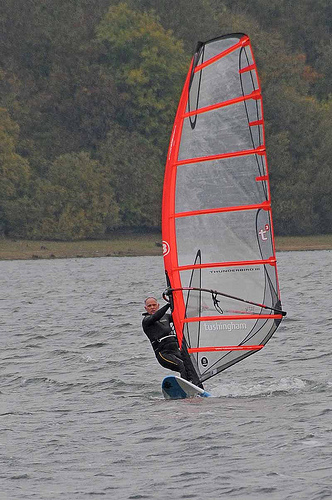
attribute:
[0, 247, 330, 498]
ocean — blue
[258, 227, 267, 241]
letter — red, white, t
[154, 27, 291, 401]
windsurfing board — clashing colors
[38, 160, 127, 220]
green tree — large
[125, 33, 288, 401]
windsurfer — determined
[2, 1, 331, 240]
trees — green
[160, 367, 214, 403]
board — blue, white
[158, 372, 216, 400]
surfboard — blue and white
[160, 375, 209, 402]
surf board — blue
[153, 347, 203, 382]
pants — black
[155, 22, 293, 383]
sail — red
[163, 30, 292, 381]
windsurfing sail — orange, black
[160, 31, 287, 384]
sail — clear, red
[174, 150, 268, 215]
panel — clear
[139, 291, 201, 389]
man — windsurfing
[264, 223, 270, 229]
3 — number